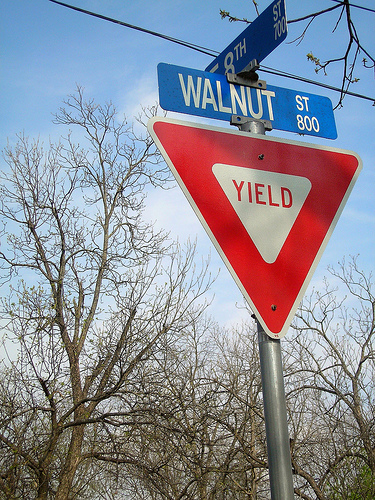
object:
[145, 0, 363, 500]
sign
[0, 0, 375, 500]
tree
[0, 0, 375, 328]
sky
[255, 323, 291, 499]
pole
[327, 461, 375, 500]
leave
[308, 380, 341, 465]
corner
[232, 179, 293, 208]
word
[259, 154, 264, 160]
bolt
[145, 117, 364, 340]
sig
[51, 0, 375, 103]
line